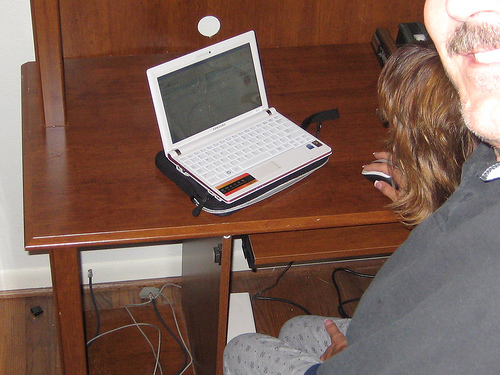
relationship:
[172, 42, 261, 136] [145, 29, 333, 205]
screen of laptop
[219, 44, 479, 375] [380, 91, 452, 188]
woman has hair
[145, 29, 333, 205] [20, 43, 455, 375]
laptop on desk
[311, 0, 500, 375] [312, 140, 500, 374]
man wearing black shirt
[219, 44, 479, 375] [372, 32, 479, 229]
woman with hair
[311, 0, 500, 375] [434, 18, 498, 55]
man with a mustache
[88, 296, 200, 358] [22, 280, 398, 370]
cords on floor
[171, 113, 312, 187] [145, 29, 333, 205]
keyboard on laptop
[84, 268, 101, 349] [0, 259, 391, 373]
cords laying on ground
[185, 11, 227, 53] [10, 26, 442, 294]
hole in back of desk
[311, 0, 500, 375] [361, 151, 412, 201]
man has hand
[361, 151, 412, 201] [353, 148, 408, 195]
hand on mouse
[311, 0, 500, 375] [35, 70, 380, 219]
man at desk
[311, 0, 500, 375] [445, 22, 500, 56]
man has mustache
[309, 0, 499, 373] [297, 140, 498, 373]
man has black shirt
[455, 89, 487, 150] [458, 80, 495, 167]
hair on mans chin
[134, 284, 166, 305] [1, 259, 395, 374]
wire on floor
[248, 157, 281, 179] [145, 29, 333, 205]
mouse pad on laptop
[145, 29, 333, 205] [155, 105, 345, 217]
laptop sitting on laptop case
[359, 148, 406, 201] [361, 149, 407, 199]
hand on mouse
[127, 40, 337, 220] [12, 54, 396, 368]
laptop on desk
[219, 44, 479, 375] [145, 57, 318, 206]
woman looking at computer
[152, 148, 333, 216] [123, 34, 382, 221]
laptop case under laptop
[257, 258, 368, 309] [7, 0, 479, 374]
cords are under desk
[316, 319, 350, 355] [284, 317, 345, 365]
hands between legs.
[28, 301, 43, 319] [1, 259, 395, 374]
piece on floor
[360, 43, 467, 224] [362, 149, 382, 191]
woman has fingernail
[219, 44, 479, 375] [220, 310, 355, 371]
woman has pajamas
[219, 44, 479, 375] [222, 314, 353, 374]
woman wears pajama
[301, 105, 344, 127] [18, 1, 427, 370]
strap on table